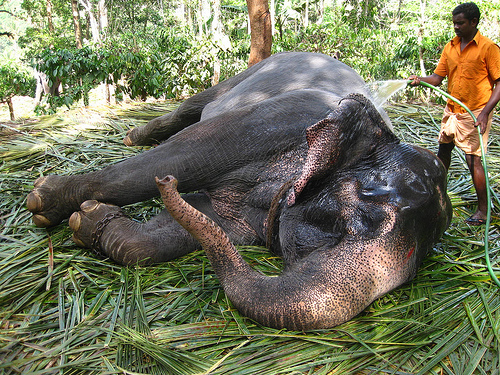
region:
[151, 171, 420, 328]
the trunk of the elephant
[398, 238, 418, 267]
the blood on the face of the elephant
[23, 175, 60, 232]
the nails of the elephants foot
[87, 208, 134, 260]
the chain on the elephants ankle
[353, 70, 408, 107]
the water spraying from the hose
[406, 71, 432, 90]
the green hose in the mans hand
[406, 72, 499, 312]
the green hose spraying the elephant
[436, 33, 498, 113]
the orange shirt on the man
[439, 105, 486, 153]
the shorts of the man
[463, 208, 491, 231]
the black flip flop on the foot of the man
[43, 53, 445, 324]
an elephant laying on the ground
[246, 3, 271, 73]
the trunk of the tree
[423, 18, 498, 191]
a man wearing an orange shirt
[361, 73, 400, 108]
water coming out of the hose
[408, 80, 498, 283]
a green hose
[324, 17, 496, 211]
a man spraying an elephant with a hose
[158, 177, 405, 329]
the trunk of the elephant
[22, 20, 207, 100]
green trees in the background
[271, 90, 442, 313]
the head of the elephant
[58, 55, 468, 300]
an elephant getting sprayed with water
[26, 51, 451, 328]
elephant laying on the palm leaves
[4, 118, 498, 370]
ground covered in palm fronds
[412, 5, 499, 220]
man in orange shirt and peach shorts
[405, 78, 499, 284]
a green garden hose spraying water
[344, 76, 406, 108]
water coming from the hose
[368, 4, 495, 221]
a man watering down the elephant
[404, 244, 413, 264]
red dot on elephant's forehead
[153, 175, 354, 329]
the elephant's trunk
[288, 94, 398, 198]
the elephant's right ear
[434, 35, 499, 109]
a short-sleeve orange shirt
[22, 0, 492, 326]
an elephant getting a bath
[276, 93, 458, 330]
the head of an elephant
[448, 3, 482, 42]
the head of a man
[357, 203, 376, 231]
the eye of an elephant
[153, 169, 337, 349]
the trunk of an elephant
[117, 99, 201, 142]
the leg of an elephant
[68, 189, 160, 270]
the leg of an elephant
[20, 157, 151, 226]
the leg of an elephant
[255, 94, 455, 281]
this is an elephant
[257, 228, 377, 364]
this is a trunk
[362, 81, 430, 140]
this is some water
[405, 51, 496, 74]
this is an orange shirt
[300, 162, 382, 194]
this is an ear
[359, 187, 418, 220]
this is an eye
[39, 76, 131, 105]
this is an old tree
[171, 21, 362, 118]
this is a tree trunk